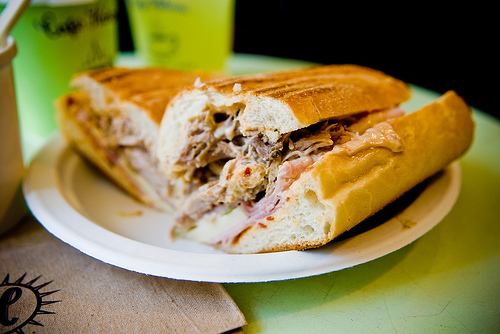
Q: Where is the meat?
A: Inside the sandwich.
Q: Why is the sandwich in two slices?
A: It's easier to manage.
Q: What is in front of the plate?
A: A napkin.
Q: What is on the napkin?
A: A sun.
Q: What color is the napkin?
A: Brown.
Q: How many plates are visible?
A: One.